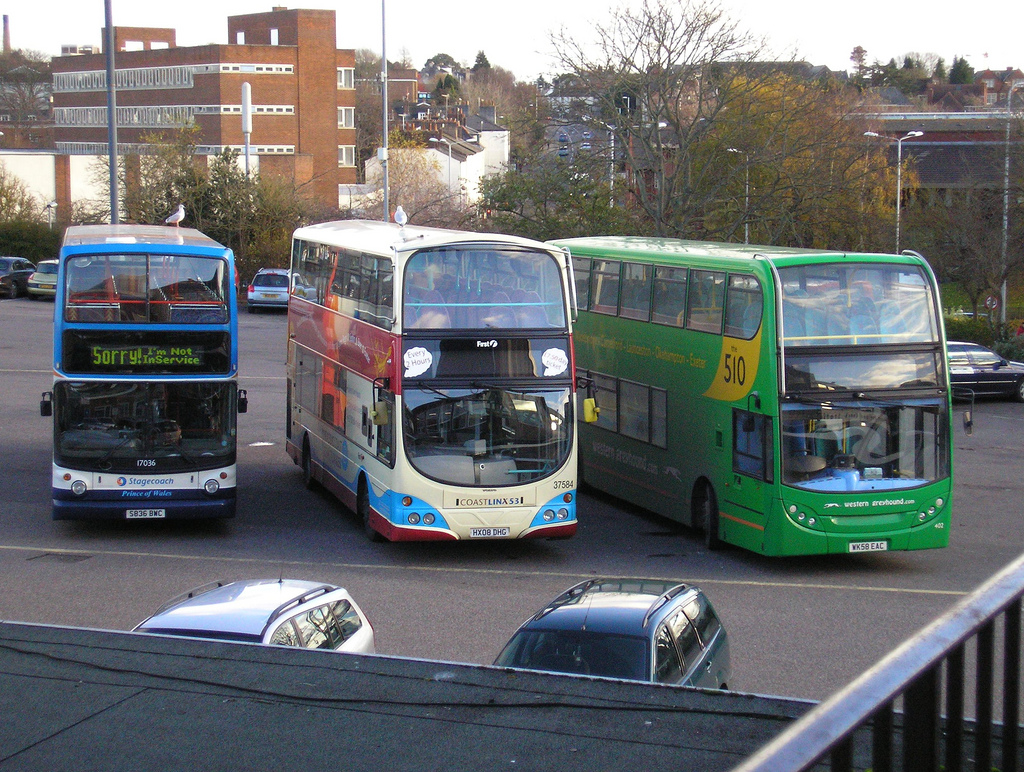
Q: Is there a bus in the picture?
A: Yes, there is a bus.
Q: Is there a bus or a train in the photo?
A: Yes, there is a bus.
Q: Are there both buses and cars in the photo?
A: Yes, there are both a bus and a car.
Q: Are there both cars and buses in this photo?
A: Yes, there are both a bus and a car.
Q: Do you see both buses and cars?
A: Yes, there are both a bus and a car.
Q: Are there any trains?
A: No, there are no trains.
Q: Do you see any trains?
A: No, there are no trains.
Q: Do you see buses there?
A: Yes, there is a bus.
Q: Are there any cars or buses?
A: Yes, there is a bus.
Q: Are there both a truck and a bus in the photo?
A: No, there is a bus but no trucks.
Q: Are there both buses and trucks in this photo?
A: No, there is a bus but no trucks.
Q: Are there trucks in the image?
A: No, there are no trucks.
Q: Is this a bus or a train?
A: This is a bus.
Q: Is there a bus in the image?
A: Yes, there is a bus.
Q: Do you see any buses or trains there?
A: Yes, there is a bus.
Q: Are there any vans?
A: No, there are no vans.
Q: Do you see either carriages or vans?
A: No, there are no vans or carriages.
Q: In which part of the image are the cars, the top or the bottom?
A: The cars are in the bottom of the image.